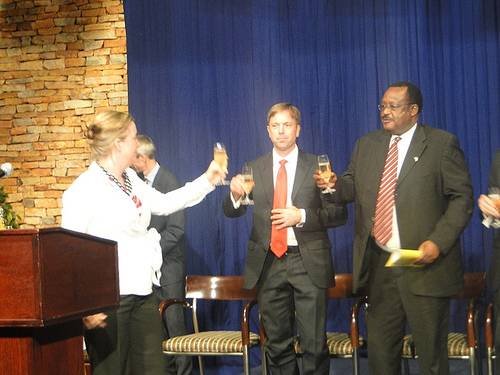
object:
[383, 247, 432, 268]
book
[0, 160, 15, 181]
microphone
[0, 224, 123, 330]
podium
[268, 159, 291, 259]
tie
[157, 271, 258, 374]
chairs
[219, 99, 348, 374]
man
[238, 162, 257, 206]
glass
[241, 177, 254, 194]
wine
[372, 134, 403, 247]
tie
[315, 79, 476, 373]
man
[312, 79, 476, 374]
speakers